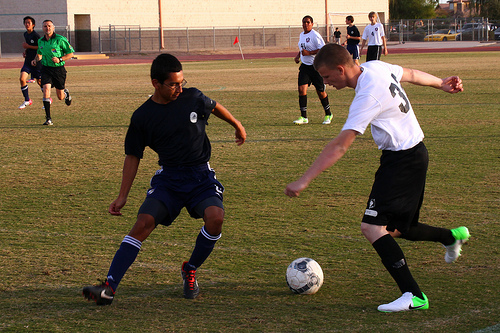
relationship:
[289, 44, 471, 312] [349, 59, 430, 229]
man in black and white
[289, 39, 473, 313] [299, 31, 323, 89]
man in black and white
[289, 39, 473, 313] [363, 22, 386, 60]
man in black and white